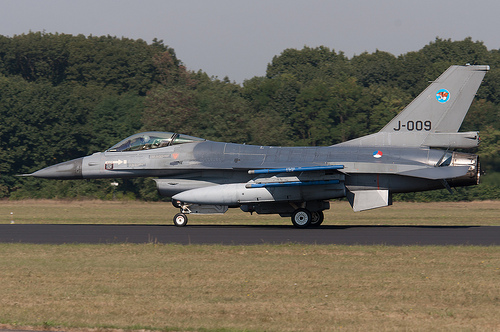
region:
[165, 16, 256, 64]
The sky is clear.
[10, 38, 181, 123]
The trees have leaves.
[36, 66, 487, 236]
The jet is grey.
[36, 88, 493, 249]
The jet is on the runway.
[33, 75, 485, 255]
The wheels are down.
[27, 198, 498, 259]
The runway is clear.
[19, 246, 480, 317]
The grass is brown.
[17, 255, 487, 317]
The grass is dying.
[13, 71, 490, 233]
The jet is trying to take off.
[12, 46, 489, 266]
The jet is military.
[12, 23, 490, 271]
a jet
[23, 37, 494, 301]
a grey jet outside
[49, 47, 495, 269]
a jet on runway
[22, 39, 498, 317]
a grey jet during the day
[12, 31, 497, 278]
a grey airplane during the day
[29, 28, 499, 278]
a grey airplane on the ground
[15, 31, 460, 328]
a grey airplane on its wheels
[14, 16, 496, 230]
a grey airplane with wheels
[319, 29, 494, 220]
a grey airplane tail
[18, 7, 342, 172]
trees in the distance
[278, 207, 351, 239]
two back wheels of fighter jet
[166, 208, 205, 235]
a front wheel of jet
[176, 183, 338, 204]
a missle on a fighter jet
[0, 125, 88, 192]
the front nose of a fighter jet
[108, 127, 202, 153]
the cockpit of a fighter jet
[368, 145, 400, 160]
red white and blue brand on side of jet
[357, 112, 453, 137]
a number in black identifies the fighter jet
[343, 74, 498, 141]
the tail of a fighter jet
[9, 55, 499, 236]
a grey fighter jet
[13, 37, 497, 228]
green trees in background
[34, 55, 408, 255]
the plane is grey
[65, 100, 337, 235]
the plane is grey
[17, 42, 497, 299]
Military jet on runway.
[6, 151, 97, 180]
Pointed nose on the front.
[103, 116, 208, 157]
A clear aircraft canopy.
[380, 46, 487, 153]
Tail section on jet.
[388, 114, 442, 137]
J-009 in black on tail of airplane.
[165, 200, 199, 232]
Front wheel on a jet.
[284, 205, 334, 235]
Back wheels on a jet.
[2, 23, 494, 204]
Green trees in the background.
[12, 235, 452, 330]
Brown grass beside runway.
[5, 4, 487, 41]
Clear blue cloudless sky.